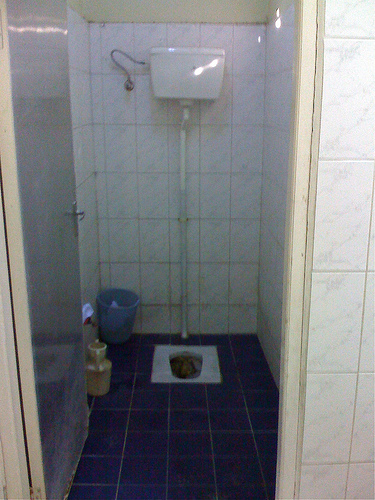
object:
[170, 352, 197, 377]
wastes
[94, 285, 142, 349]
bin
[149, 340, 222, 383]
toilet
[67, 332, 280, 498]
floor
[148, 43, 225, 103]
tank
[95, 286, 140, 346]
basket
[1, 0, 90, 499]
door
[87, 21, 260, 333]
wall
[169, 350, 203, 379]
hole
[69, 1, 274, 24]
ceiling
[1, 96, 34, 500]
door edge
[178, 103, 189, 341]
pipe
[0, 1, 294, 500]
bathroom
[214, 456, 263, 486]
tile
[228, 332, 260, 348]
tile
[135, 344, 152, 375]
tile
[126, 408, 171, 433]
tile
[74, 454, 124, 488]
tile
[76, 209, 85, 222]
handle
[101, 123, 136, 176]
tile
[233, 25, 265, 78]
tile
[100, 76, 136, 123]
tile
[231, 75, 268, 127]
tile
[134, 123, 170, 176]
tile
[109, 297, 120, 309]
garbage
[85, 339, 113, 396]
jug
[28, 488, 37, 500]
hinge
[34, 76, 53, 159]
surface